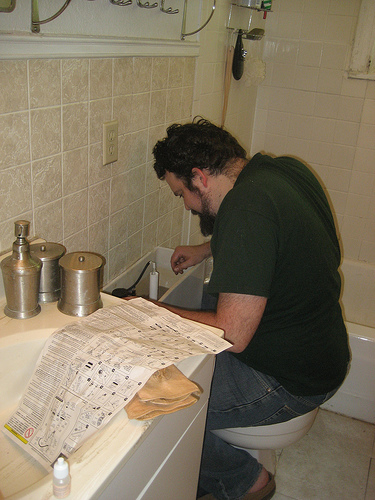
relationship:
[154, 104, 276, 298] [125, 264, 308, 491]
man on toilet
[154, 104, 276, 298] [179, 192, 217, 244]
man has beard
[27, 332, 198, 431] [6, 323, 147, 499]
newspaper on sink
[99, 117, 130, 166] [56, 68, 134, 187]
outlet on wall